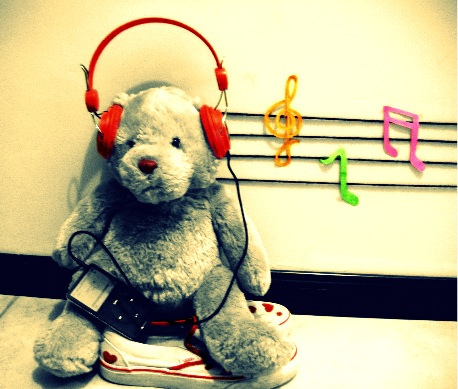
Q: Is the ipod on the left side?
A: Yes, the ipod is on the left of the image.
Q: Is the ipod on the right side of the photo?
A: No, the ipod is on the left of the image.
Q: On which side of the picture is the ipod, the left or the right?
A: The ipod is on the left of the image.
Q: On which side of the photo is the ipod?
A: The ipod is on the left of the image.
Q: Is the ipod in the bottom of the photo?
A: Yes, the ipod is in the bottom of the image.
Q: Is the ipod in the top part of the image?
A: No, the ipod is in the bottom of the image.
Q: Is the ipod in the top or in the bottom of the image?
A: The ipod is in the bottom of the image.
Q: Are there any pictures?
A: No, there are no pictures.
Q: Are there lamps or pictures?
A: No, there are no pictures or lamps.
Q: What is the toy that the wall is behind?
A: The toy is a teddy bear.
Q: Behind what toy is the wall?
A: The wall is behind the teddy bear.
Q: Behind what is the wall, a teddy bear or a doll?
A: The wall is behind a teddy bear.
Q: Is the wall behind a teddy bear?
A: Yes, the wall is behind a teddy bear.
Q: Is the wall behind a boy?
A: No, the wall is behind a teddy bear.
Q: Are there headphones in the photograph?
A: Yes, there are headphones.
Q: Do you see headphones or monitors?
A: Yes, there are headphones.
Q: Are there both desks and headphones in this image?
A: No, there are headphones but no desks.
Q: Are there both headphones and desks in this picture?
A: No, there are headphones but no desks.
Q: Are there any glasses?
A: No, there are no glasses.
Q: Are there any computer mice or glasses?
A: No, there are no glasses or computer mice.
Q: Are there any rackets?
A: No, there are no rackets.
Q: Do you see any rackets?
A: No, there are no rackets.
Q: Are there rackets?
A: No, there are no rackets.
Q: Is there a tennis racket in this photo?
A: No, there are no rackets.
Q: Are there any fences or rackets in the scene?
A: No, there are no rackets or fences.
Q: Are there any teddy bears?
A: Yes, there is a teddy bear.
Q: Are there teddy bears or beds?
A: Yes, there is a teddy bear.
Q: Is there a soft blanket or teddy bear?
A: Yes, there is a soft teddy bear.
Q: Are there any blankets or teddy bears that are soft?
A: Yes, the teddy bear is soft.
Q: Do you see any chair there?
A: No, there are no chairs.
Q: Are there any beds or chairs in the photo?
A: No, there are no chairs or beds.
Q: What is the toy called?
A: The toy is a teddy bear.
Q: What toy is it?
A: The toy is a teddy bear.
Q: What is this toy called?
A: This is a teddy bear.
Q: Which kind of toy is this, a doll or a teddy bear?
A: This is a teddy bear.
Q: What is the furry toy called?
A: The toy is a teddy bear.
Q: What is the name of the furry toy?
A: The toy is a teddy bear.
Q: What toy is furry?
A: The toy is a teddy bear.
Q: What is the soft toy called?
A: The toy is a teddy bear.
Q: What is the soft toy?
A: The toy is a teddy bear.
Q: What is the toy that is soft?
A: The toy is a teddy bear.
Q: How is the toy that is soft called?
A: The toy is a teddy bear.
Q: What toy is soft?
A: The toy is a teddy bear.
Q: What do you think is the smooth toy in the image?
A: The toy is a teddy bear.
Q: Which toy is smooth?
A: The toy is a teddy bear.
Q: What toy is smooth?
A: The toy is a teddy bear.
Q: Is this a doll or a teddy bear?
A: This is a teddy bear.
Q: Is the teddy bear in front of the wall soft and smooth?
A: Yes, the teddy bear is soft and smooth.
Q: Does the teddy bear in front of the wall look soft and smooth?
A: Yes, the teddy bear is soft and smooth.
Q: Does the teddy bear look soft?
A: Yes, the teddy bear is soft.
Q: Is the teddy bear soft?
A: Yes, the teddy bear is soft.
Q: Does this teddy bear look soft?
A: Yes, the teddy bear is soft.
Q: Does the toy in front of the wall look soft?
A: Yes, the teddy bear is soft.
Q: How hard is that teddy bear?
A: The teddy bear is soft.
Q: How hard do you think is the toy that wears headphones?
A: The teddy bear is soft.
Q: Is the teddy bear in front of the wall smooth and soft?
A: Yes, the teddy bear is smooth and soft.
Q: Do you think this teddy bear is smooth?
A: Yes, the teddy bear is smooth.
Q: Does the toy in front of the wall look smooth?
A: Yes, the teddy bear is smooth.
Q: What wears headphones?
A: The teddy bear wears headphones.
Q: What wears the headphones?
A: The teddy bear wears headphones.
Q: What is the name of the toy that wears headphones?
A: The toy is a teddy bear.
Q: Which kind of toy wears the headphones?
A: The toy is a teddy bear.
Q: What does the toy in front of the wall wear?
A: The teddy bear wears headphones.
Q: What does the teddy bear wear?
A: The teddy bear wears headphones.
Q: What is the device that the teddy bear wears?
A: The device is headphones.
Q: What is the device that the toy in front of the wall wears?
A: The device is headphones.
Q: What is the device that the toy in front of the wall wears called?
A: The device is headphones.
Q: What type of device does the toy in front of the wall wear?
A: The teddy bear wears headphones.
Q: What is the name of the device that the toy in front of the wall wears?
A: The device is headphones.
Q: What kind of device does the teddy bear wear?
A: The teddy bear wears headphones.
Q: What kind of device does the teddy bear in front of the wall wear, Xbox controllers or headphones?
A: The teddy bear wears headphones.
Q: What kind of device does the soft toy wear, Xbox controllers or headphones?
A: The teddy bear wears headphones.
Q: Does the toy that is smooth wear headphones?
A: Yes, the teddy bear wears headphones.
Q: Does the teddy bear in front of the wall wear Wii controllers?
A: No, the teddy bear wears headphones.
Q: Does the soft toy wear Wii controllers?
A: No, the teddy bear wears headphones.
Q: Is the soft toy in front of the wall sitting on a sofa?
A: No, the teddy bear is sitting on the shoe.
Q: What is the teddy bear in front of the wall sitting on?
A: The teddy bear is sitting on the shoe.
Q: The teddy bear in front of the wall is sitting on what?
A: The teddy bear is sitting on the shoe.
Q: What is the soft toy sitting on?
A: The teddy bear is sitting on the shoe.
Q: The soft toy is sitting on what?
A: The teddy bear is sitting on the shoe.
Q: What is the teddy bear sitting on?
A: The teddy bear is sitting on the shoe.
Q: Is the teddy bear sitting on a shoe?
A: Yes, the teddy bear is sitting on a shoe.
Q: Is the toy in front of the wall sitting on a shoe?
A: Yes, the teddy bear is sitting on a shoe.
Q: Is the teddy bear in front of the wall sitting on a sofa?
A: No, the teddy bear is sitting on a shoe.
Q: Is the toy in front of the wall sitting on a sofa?
A: No, the teddy bear is sitting on a shoe.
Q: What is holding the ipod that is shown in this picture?
A: The teddy bear is holding the ipod.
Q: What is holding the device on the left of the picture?
A: The teddy bear is holding the ipod.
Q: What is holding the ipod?
A: The teddy bear is holding the ipod.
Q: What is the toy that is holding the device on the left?
A: The toy is a teddy bear.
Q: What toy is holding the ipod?
A: The toy is a teddy bear.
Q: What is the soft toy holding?
A: The teddy bear is holding the ipod.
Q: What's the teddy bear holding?
A: The teddy bear is holding the ipod.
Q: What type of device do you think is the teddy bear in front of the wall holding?
A: The teddy bear is holding the ipod.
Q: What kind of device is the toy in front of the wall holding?
A: The teddy bear is holding the ipod.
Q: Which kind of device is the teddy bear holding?
A: The teddy bear is holding the ipod.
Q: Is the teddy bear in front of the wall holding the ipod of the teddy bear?
A: Yes, the teddy bear is holding the ipod.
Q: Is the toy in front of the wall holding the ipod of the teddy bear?
A: Yes, the teddy bear is holding the ipod.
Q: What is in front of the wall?
A: The teddy bear is in front of the wall.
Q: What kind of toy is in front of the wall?
A: The toy is a teddy bear.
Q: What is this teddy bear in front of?
A: The teddy bear is in front of the wall.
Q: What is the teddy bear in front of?
A: The teddy bear is in front of the wall.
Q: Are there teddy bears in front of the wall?
A: Yes, there is a teddy bear in front of the wall.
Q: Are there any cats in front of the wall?
A: No, there is a teddy bear in front of the wall.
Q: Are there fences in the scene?
A: No, there are no fences.